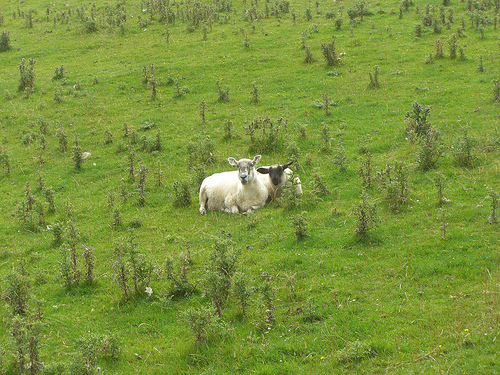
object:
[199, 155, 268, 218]
sheep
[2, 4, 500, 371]
field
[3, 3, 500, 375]
grass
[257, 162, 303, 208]
sheep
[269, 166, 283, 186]
black face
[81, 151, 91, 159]
flowers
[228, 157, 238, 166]
ears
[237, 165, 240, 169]
eyes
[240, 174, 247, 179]
nose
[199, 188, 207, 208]
legs